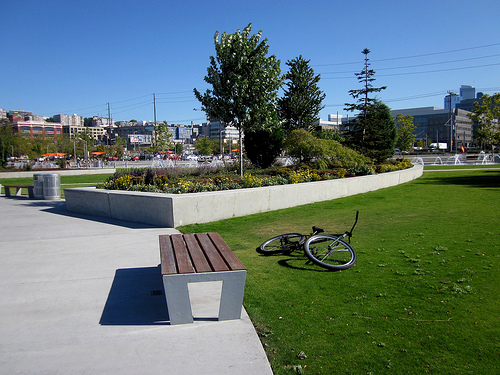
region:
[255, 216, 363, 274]
black bicycle on the floor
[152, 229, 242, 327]
white and wooden bench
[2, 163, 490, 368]
little square with green grass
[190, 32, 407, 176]
small trees in the back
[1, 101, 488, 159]
a bunch of small buildings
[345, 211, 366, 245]
black handlebar of bicycle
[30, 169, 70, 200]
gray metal dump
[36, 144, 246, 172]
orange umbrellas on a square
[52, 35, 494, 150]
gray large electricity poles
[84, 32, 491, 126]
gray electrical wires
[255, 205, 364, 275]
Bicycle lying on grass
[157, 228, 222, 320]
Stone bench with wood slat seat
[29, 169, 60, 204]
Two large steel trash cans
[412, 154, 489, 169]
Several sprinklers in background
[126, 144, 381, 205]
Various shrubs in concrete plot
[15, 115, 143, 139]
Many buildings packed together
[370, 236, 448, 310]
Clover growing in small patches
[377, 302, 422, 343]
Small brown leaves on grass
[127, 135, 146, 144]
Billboard sign in background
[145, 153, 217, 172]
Several small sprinklers in background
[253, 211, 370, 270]
Bicycle laying on the green grass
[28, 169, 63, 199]
Two silver garbage cans at a park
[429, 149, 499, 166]
Water fountain at a distance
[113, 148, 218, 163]
Cars parked at a distance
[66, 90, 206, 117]
Electric wires running on poles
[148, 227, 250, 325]
Brown and white bench at a park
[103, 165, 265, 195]
Colorful flowerbed at a park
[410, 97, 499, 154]
Multiple story buildings at a distance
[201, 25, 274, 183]
Big tree with green foliage on it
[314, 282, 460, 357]
Green short grass on the ground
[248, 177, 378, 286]
a bike is on the grass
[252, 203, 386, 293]
the bike is laying down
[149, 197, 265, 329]
the bench is empty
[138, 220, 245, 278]
the bench is brown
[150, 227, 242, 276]
the bench top is made of wood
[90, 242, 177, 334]
shadow on the ground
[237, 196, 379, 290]
the bike is black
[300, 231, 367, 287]
the wheel is black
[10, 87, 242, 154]
buildings in the background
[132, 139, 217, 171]
cars are parked in the background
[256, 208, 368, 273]
Bike on its side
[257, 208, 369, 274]
Bike is on its side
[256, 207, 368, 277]
Bicycle on its side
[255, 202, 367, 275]
Bicycle is on its side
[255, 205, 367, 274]
Bike on the grass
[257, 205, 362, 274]
Bike is on the grass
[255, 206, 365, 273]
Bicycle on the grass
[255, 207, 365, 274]
Bicycle is on the grass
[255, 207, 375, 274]
Bike on the lawn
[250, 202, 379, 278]
Bicycle on the lawn